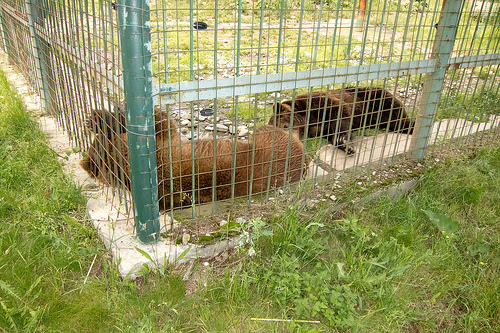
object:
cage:
[1, 0, 500, 280]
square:
[232, 148, 256, 169]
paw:
[342, 144, 358, 158]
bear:
[264, 84, 416, 156]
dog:
[78, 100, 313, 206]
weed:
[0, 0, 499, 333]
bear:
[78, 103, 312, 212]